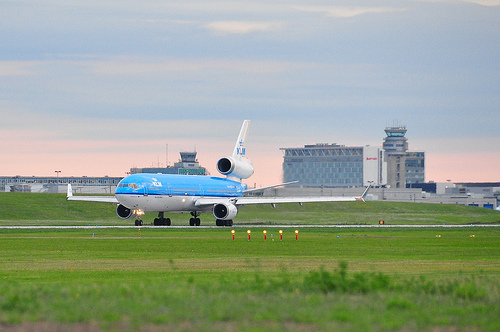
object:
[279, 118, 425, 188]
building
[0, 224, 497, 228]
large runway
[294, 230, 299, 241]
light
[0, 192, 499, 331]
grass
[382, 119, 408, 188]
tower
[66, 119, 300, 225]
plane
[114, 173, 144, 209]
nose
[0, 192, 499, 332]
road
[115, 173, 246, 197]
blue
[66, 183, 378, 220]
white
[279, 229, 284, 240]
light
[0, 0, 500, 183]
sky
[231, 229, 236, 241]
light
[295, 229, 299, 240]
post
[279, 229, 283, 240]
post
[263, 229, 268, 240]
post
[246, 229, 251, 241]
post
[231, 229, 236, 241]
post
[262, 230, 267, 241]
light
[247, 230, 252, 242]
light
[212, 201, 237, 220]
engine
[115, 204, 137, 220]
engine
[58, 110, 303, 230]
airplane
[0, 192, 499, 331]
ground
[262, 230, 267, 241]
warning light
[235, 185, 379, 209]
wing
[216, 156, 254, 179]
engine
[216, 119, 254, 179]
tail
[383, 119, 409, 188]
airport tower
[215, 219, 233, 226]
wheel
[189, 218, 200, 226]
wheel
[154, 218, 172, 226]
wheel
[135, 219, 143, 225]
wheel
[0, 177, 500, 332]
airport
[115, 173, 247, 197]
top half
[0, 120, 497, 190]
lower section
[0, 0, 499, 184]
cloud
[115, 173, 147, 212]
front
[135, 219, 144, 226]
front tire